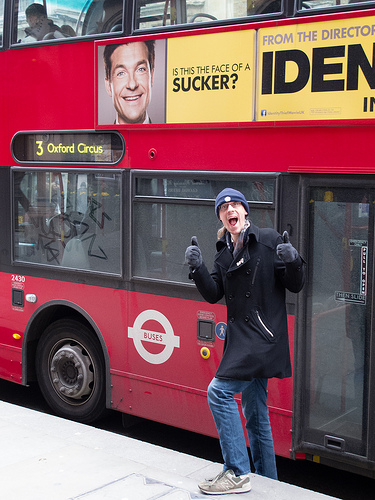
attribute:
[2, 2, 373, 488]
bus — two story, red, big, double decker, city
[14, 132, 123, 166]
sign — information, digital, destination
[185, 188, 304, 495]
man — happy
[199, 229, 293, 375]
coat — black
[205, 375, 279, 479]
jeans — blue, denim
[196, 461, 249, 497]
foot wear — brown, white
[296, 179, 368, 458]
door — sliding, glass, entry, closed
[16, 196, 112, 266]
graffiti — dust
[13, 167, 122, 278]
window — dusty, dirty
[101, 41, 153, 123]
actor — comedic, jason bateman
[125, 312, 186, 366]
sign — red, bus, white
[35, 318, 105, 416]
tire — black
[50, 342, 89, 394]
hubcap — grey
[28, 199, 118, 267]
drawings — strange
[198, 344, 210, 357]
button — yellow, small, reflective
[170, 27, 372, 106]
ad — yellow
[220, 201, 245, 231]
face — smiling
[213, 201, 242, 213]
eyes — blue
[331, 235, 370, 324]
signs — instructive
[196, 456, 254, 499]
shoe — tennis, white, grey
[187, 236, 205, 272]
glove — blue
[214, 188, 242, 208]
cap — dark blue, skull, blue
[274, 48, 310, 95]
letter — capital, black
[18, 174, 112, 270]
writing — black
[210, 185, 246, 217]
hat — blue, ski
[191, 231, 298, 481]
attire — winter